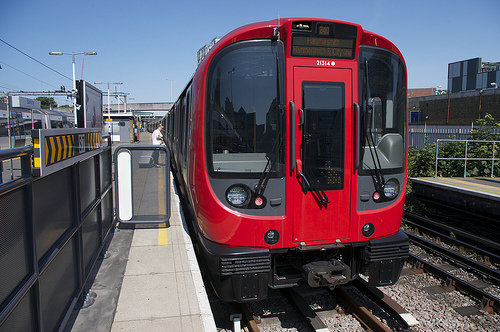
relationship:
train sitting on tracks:
[168, 27, 431, 321] [222, 260, 425, 328]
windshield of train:
[208, 32, 288, 234] [168, 14, 404, 287]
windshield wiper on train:
[254, 134, 288, 204] [168, 14, 404, 287]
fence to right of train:
[433, 137, 498, 181] [168, 14, 404, 287]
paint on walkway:
[155, 150, 170, 245] [57, 130, 216, 329]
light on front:
[228, 183, 254, 209] [192, 17, 410, 308]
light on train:
[228, 183, 254, 209] [168, 14, 404, 287]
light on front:
[382, 178, 401, 200] [192, 17, 410, 308]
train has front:
[168, 14, 404, 287] [192, 17, 410, 308]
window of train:
[202, 37, 286, 178] [168, 14, 404, 287]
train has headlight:
[168, 14, 404, 287] [227, 181, 251, 209]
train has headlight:
[168, 14, 404, 287] [380, 178, 401, 199]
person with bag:
[148, 123, 166, 158] [137, 144, 157, 168]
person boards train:
[148, 123, 166, 158] [168, 14, 404, 287]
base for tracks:
[390, 258, 498, 330] [393, 209, 498, 329]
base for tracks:
[390, 258, 498, 330] [222, 275, 425, 328]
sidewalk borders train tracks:
[75, 127, 215, 329] [228, 280, 418, 330]